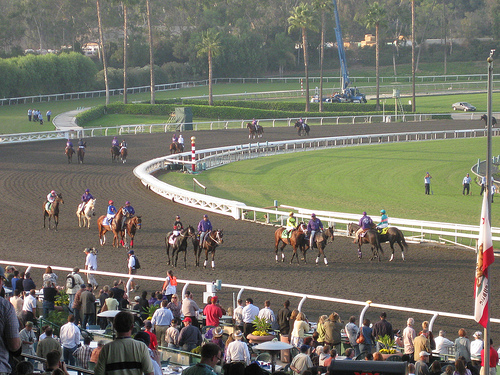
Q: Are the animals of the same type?
A: Yes, all the animals are horses.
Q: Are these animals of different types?
A: No, all the animals are horses.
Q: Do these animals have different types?
A: No, all the animals are horses.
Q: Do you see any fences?
A: Yes, there is a fence.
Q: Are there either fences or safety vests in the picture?
A: Yes, there is a fence.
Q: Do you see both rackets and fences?
A: No, there is a fence but no rackets.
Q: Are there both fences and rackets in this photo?
A: No, there is a fence but no rackets.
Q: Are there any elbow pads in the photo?
A: No, there are no elbow pads.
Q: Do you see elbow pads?
A: No, there are no elbow pads.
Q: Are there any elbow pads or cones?
A: No, there are no elbow pads or cones.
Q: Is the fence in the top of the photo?
A: Yes, the fence is in the top of the image.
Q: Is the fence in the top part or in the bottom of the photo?
A: The fence is in the top of the image.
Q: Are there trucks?
A: Yes, there is a truck.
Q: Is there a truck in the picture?
A: Yes, there is a truck.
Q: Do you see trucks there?
A: Yes, there is a truck.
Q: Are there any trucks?
A: Yes, there is a truck.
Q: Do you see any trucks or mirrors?
A: Yes, there is a truck.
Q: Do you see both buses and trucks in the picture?
A: No, there is a truck but no buses.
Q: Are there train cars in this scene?
A: No, there are no train cars.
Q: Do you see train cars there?
A: No, there are no train cars.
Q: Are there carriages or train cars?
A: No, there are no train cars or carriages.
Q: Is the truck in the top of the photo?
A: Yes, the truck is in the top of the image.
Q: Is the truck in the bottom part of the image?
A: No, the truck is in the top of the image.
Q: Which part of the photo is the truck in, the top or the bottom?
A: The truck is in the top of the image.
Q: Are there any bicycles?
A: No, there are no bicycles.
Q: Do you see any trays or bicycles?
A: No, there are no bicycles or trays.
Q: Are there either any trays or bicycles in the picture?
A: No, there are no bicycles or trays.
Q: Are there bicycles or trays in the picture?
A: No, there are no bicycles or trays.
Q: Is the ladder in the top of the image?
A: Yes, the ladder is in the top of the image.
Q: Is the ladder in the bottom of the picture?
A: No, the ladder is in the top of the image.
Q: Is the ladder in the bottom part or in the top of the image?
A: The ladder is in the top of the image.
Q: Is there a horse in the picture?
A: Yes, there is a horse.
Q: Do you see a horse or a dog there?
A: Yes, there is a horse.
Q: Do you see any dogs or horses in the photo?
A: Yes, there is a horse.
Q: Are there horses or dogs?
A: Yes, there is a horse.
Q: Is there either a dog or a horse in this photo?
A: Yes, there is a horse.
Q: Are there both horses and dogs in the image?
A: No, there is a horse but no dogs.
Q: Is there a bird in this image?
A: No, there are no birds.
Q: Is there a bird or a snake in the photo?
A: No, there are no birds or snakes.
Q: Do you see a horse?
A: Yes, there is a horse.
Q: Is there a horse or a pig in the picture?
A: Yes, there is a horse.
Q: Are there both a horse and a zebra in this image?
A: No, there is a horse but no zebras.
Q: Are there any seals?
A: No, there are no seals.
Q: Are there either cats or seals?
A: No, there are no seals or cats.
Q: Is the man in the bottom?
A: Yes, the man is in the bottom of the image.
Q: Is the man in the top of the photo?
A: No, the man is in the bottom of the image.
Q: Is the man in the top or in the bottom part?
A: The man is in the bottom of the image.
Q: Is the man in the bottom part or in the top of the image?
A: The man is in the bottom of the image.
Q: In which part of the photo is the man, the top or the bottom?
A: The man is in the bottom of the image.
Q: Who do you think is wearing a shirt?
A: The man is wearing a shirt.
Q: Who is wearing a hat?
A: The man is wearing a hat.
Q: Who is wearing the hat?
A: The man is wearing a hat.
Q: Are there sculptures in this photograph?
A: No, there are no sculptures.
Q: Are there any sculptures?
A: No, there are no sculptures.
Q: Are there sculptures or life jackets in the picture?
A: No, there are no sculptures or life jackets.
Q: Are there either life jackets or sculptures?
A: No, there are no sculptures or life jackets.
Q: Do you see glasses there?
A: No, there are no glasses.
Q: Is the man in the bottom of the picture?
A: Yes, the man is in the bottom of the image.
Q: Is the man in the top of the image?
A: No, the man is in the bottom of the image.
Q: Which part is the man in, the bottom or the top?
A: The man is in the bottom of the image.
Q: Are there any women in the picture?
A: Yes, there is a woman.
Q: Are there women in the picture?
A: Yes, there is a woman.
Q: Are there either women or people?
A: Yes, there is a woman.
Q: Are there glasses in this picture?
A: No, there are no glasses.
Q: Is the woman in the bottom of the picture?
A: Yes, the woman is in the bottom of the image.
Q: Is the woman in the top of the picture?
A: No, the woman is in the bottom of the image.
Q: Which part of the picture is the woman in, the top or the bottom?
A: The woman is in the bottom of the image.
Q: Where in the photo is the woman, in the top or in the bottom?
A: The woman is in the bottom of the image.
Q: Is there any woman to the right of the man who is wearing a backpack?
A: Yes, there is a woman to the right of the man.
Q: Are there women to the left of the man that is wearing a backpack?
A: No, the woman is to the right of the man.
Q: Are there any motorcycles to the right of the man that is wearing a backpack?
A: No, there is a woman to the right of the man.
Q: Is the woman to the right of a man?
A: Yes, the woman is to the right of a man.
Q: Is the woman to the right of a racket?
A: No, the woman is to the right of a man.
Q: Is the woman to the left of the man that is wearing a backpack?
A: No, the woman is to the right of the man.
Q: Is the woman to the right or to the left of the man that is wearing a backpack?
A: The woman is to the right of the man.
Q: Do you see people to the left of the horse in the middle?
A: Yes, there is a person to the left of the horse.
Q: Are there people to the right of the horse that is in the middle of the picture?
A: No, the person is to the left of the horse.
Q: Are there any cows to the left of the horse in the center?
A: No, there is a person to the left of the horse.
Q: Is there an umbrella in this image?
A: No, there are no umbrellas.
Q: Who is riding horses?
A: The people are riding horses.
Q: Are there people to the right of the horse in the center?
A: Yes, there are people to the right of the horse.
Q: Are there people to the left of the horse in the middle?
A: No, the people are to the right of the horse.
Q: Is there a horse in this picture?
A: Yes, there are horses.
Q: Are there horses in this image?
A: Yes, there are horses.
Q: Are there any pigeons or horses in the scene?
A: Yes, there are horses.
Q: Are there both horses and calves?
A: No, there are horses but no calves.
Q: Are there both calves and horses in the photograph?
A: No, there are horses but no calves.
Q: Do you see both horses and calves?
A: No, there are horses but no calves.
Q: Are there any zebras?
A: No, there are no zebras.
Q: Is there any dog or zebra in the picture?
A: No, there are no zebras or dogs.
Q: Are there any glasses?
A: No, there are no glasses.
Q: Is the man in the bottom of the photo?
A: Yes, the man is in the bottom of the image.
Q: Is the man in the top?
A: No, the man is in the bottom of the image.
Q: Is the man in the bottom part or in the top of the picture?
A: The man is in the bottom of the image.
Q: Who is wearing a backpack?
A: The man is wearing a backpack.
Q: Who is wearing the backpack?
A: The man is wearing a backpack.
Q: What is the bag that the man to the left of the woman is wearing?
A: The bag is a backpack.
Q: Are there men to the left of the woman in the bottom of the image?
A: Yes, there is a man to the left of the woman.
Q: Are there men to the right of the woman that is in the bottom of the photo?
A: No, the man is to the left of the woman.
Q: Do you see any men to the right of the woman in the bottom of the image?
A: No, the man is to the left of the woman.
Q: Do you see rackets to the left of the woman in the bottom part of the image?
A: No, there is a man to the left of the woman.